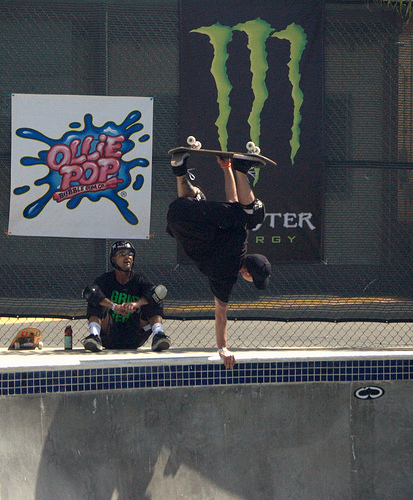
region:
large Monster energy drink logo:
[182, 24, 319, 267]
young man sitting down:
[82, 242, 174, 353]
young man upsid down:
[159, 128, 298, 369]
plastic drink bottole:
[60, 321, 75, 350]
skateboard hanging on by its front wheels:
[2, 324, 52, 355]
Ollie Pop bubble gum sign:
[0, 78, 163, 245]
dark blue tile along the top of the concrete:
[0, 358, 412, 401]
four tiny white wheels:
[182, 130, 271, 154]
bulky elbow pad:
[141, 274, 173, 307]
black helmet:
[100, 238, 139, 274]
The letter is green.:
[186, 15, 318, 197]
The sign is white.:
[9, 84, 152, 243]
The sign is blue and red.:
[10, 96, 149, 240]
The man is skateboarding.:
[161, 134, 280, 372]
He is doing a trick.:
[158, 125, 280, 366]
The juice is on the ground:
[56, 312, 79, 353]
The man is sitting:
[79, 231, 170, 364]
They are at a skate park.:
[1, 15, 387, 496]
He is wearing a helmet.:
[80, 227, 193, 355]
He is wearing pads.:
[75, 225, 179, 367]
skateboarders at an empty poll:
[71, 132, 273, 483]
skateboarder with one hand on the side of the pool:
[167, 134, 280, 374]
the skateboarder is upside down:
[167, 131, 279, 378]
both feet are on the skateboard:
[163, 133, 278, 209]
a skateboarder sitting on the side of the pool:
[82, 237, 175, 356]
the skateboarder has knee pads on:
[179, 186, 268, 234]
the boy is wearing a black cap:
[242, 253, 272, 290]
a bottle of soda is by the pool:
[58, 321, 77, 354]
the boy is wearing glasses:
[110, 241, 140, 272]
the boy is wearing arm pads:
[81, 280, 168, 306]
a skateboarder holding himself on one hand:
[160, 135, 292, 376]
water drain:
[342, 351, 404, 426]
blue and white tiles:
[52, 367, 145, 389]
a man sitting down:
[75, 225, 178, 363]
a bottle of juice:
[59, 319, 78, 351]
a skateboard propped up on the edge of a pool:
[9, 313, 50, 359]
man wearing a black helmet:
[108, 233, 148, 272]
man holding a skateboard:
[159, 127, 283, 199]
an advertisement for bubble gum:
[4, 86, 155, 246]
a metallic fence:
[58, 19, 181, 82]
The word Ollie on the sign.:
[44, 138, 124, 162]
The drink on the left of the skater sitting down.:
[58, 322, 76, 349]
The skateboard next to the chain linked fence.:
[4, 324, 50, 351]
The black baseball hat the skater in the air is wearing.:
[240, 250, 271, 288]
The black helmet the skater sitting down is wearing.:
[109, 236, 135, 270]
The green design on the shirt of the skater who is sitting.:
[106, 285, 136, 322]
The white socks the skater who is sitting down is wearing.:
[78, 315, 159, 329]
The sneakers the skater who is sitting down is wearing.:
[82, 330, 164, 345]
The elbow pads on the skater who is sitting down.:
[83, 276, 173, 307]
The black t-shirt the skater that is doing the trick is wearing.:
[185, 208, 247, 300]